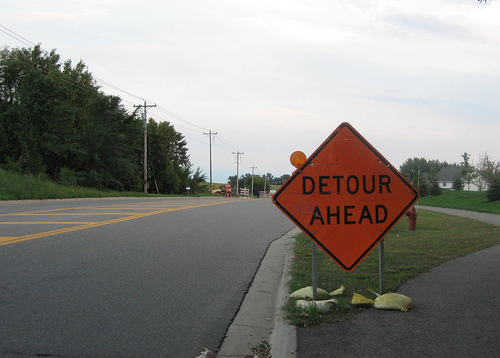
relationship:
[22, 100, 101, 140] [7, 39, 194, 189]
leaves on trees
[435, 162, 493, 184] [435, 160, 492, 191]
roof on house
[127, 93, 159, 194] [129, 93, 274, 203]
telephone pole in row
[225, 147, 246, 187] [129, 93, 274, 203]
telephone pole in row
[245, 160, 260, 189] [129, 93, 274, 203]
telephone pole in row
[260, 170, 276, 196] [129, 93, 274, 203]
telephone pole in row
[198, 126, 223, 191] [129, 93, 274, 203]
telephone pole in row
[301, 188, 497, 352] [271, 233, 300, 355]
sidewalk has curb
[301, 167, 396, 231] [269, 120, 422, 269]
lettering on sign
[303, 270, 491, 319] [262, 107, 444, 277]
bags under sign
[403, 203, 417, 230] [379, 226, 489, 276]
fire-hydrant in grass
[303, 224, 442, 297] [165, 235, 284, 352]
grass by pavement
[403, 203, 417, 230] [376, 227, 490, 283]
fire-hydrant on grass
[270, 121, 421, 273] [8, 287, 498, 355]
detour sign standing on ground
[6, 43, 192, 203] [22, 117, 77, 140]
trees have leaves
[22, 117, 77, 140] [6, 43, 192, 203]
leaves are on trees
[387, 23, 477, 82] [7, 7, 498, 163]
clouds are in sky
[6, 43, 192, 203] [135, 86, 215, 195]
trees are behind poles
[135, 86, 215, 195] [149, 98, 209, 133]
poles have wires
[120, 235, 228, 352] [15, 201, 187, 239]
pavement has lines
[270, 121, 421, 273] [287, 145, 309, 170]
detour sign has a light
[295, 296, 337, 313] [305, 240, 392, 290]
bags are around poles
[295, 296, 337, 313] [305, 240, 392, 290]
bags support poles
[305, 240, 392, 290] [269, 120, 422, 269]
poles support sign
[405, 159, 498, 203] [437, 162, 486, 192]
trees surround house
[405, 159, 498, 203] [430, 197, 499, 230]
trees are behind sidewalk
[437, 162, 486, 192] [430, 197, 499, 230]
house behind sidewalk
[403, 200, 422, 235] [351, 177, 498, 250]
fire-hydrant on grass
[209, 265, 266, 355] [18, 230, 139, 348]
border next to street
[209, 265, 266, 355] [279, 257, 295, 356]
border next to curb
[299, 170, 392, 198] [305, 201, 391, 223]
word on top of word